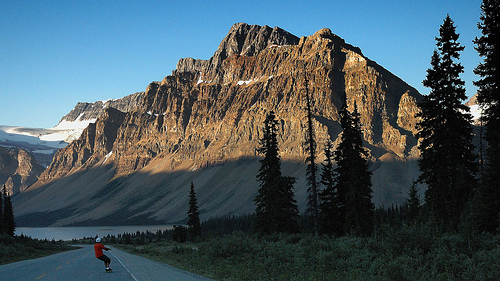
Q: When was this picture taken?
A: Daytime.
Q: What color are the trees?
A: Green.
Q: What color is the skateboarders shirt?
A: Red.